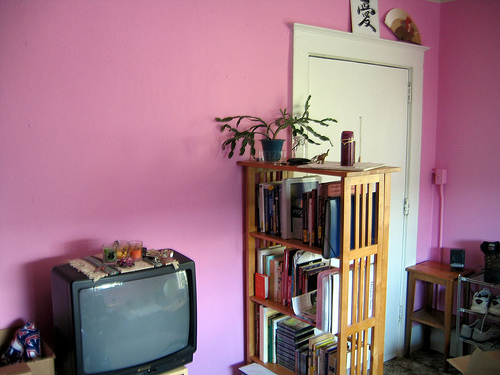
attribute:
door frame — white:
[291, 22, 430, 359]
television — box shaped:
[44, 251, 208, 362]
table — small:
[401, 247, 461, 365]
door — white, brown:
[288, 21, 432, 373]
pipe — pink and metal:
[414, 176, 474, 231]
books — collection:
[253, 175, 379, 259]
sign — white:
[349, 0, 377, 35]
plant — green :
[217, 108, 320, 168]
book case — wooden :
[236, 132, 392, 372]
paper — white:
[350, 1, 382, 41]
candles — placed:
[101, 235, 144, 264]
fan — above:
[374, 9, 414, 41]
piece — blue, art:
[4, 316, 47, 358]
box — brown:
[0, 359, 60, 367]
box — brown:
[0, 339, 57, 374]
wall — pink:
[91, 163, 220, 276]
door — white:
[309, 54, 411, 368]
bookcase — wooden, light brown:
[233, 154, 402, 373]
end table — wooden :
[403, 260, 482, 361]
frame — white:
[289, 20, 427, 366]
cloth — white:
[72, 247, 177, 281]